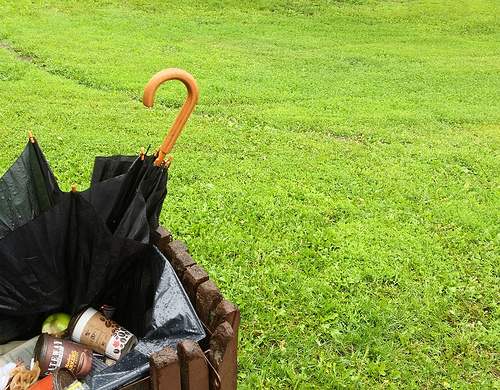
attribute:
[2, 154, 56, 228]
drops — water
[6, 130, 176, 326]
canopy — fold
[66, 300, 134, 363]
cup — foam, paper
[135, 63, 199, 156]
hook — brown, wooden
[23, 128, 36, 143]
spoke — wood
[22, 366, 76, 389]
cup — orange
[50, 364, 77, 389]
lid — brown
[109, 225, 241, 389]
trash bin — brown, wooden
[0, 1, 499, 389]
grass — neatly trimmed, green, thick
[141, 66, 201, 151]
handle — wood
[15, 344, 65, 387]
cup — orange, trash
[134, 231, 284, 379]
can — brown, wood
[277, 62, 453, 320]
grass — green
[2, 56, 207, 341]
umbrella — black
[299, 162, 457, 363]
grass — green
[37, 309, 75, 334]
apple — green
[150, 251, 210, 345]
trash bag — black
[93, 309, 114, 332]
design — blown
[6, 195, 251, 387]
trash can — wood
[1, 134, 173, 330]
umbrella — black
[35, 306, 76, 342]
apple — green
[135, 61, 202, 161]
handle — brown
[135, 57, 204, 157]
handle — brown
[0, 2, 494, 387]
field — green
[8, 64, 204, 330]
umbrella — black